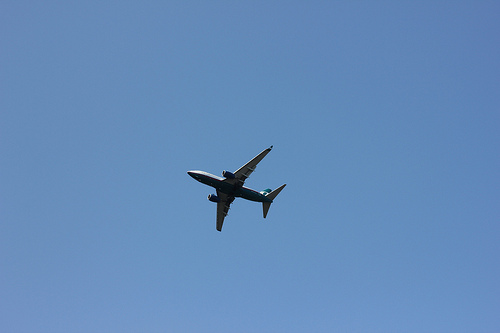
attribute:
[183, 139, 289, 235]
airplane — silver, solo, flying, twin engine, transporting, gray, large, commercial, jumbo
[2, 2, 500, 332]
sky — blue, clear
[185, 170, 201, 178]
tip — silver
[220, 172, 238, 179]
engine — silver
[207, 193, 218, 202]
engine — silver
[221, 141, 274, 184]
wing — silver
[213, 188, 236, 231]
wing — silver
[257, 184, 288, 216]
tail — silver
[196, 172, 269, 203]
body — silver